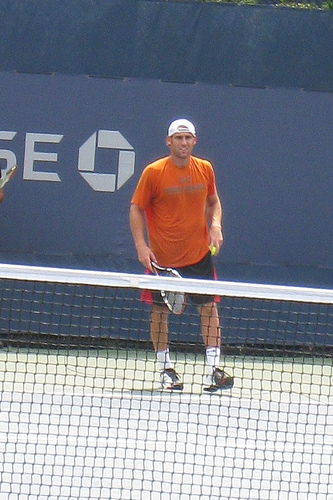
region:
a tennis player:
[131, 117, 235, 411]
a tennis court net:
[0, 256, 330, 490]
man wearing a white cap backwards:
[162, 117, 202, 138]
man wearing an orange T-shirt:
[139, 159, 216, 258]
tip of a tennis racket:
[4, 163, 22, 199]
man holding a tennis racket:
[135, 239, 191, 312]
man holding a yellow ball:
[204, 232, 231, 266]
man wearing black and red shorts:
[137, 260, 243, 300]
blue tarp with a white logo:
[0, 4, 141, 187]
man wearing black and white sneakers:
[158, 365, 240, 395]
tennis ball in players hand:
[207, 241, 219, 257]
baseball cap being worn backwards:
[167, 117, 197, 137]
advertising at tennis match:
[0, 127, 136, 193]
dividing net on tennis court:
[0, 261, 332, 498]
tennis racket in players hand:
[146, 258, 191, 316]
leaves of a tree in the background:
[265, 0, 328, 12]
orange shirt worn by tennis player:
[126, 155, 218, 268]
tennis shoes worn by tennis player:
[207, 365, 234, 386]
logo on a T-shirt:
[160, 173, 206, 202]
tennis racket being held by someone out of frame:
[0, 163, 17, 201]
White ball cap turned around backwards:
[167, 115, 198, 139]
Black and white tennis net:
[6, 263, 124, 371]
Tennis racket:
[153, 262, 189, 315]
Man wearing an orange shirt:
[129, 118, 208, 262]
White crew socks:
[150, 348, 228, 370]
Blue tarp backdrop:
[20, 20, 250, 113]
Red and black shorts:
[146, 259, 225, 308]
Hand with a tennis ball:
[203, 230, 222, 258]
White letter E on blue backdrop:
[12, 123, 64, 191]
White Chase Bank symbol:
[75, 125, 138, 197]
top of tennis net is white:
[14, 247, 331, 307]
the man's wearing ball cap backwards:
[165, 115, 207, 146]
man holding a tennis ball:
[208, 230, 231, 260]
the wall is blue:
[114, 30, 310, 107]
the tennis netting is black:
[54, 337, 329, 444]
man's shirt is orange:
[113, 161, 224, 249]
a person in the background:
[0, 164, 17, 200]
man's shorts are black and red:
[129, 247, 248, 331]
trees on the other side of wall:
[214, 0, 324, 11]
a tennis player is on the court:
[127, 116, 236, 398]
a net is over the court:
[1, 259, 331, 498]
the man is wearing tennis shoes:
[160, 366, 234, 390]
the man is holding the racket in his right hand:
[136, 242, 190, 316]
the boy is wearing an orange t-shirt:
[132, 154, 217, 267]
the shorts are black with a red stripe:
[141, 258, 220, 303]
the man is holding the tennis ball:
[208, 229, 227, 258]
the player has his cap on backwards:
[167, 116, 196, 139]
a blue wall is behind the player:
[4, 20, 329, 363]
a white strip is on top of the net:
[1, 260, 332, 315]